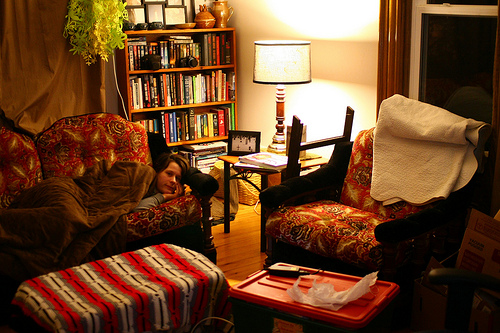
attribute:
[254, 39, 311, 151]
lamp — lit, bright, beautiful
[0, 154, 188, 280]
woman — beautiful, laying down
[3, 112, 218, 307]
couch — patterned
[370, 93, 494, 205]
blanket — white, knitted, folded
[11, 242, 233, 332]
afghan — striped, beautiful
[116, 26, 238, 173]
bookcase — wooden, full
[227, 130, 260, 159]
frame — black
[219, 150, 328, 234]
table — wood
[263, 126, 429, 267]
cushion — patterned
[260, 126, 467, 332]
chair — black, red, beautiful, wooden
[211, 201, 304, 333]
floor — brown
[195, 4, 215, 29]
pot — light brown, brown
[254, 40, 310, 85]
lampshade — white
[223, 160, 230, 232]
leg — dark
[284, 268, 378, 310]
paper — small, crumpled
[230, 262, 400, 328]
lid — red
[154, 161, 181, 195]
face — cute